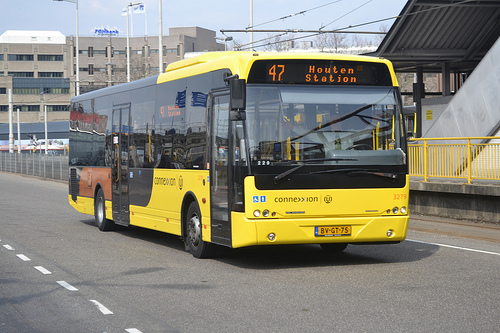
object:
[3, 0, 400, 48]
daytime sky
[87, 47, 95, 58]
windows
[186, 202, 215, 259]
bus tire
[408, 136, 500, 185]
fence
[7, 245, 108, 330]
lines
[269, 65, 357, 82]
words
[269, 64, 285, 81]
number 47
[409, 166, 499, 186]
walkway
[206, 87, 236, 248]
door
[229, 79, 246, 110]
mirror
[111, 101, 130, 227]
back door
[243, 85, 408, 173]
windshield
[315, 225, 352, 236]
license plate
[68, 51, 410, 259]
bus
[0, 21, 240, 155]
building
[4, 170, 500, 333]
street